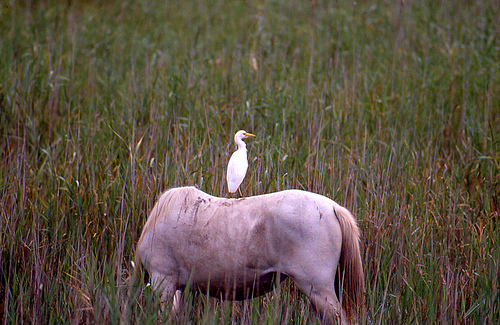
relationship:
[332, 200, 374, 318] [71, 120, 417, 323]
tail of horse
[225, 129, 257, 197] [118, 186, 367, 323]
bird on back of horse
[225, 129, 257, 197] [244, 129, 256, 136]
bird with beak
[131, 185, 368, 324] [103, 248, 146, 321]
horse has head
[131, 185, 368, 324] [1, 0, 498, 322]
horse standing in grass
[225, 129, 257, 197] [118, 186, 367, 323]
bird standing on horse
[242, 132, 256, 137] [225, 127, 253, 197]
beak of bird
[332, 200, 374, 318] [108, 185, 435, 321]
tail on horse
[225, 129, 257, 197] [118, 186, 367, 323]
bird on horse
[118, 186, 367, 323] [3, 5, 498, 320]
horse in field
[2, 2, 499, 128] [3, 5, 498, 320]
grass in field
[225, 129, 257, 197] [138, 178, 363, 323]
bird on horse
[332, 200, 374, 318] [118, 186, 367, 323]
tail on horse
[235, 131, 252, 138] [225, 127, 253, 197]
head on bird